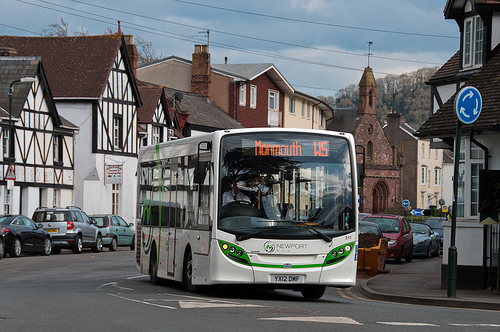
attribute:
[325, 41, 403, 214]
church — background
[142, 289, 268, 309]
markings — white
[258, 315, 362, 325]
markings — white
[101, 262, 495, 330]
markings — white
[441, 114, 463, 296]
pole — metal, green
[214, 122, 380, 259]
windscreen — large, glass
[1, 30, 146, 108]
roof — pitched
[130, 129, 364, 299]
bus — commuter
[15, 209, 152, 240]
cars — parked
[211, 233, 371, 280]
lines — green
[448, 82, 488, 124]
sign — blue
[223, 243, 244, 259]
bus headlights — pair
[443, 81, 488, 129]
sign — blue, white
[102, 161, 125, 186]
sign — elevated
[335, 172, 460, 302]
car — red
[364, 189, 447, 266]
cars — parked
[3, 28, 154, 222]
building — white, wood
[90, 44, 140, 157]
trim — dark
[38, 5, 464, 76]
sky — overcast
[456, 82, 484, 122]
sign — large, blue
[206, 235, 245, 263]
headlight — rear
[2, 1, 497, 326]
village —  quaint 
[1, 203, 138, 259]
cars — parked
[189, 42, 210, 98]
chimney — brown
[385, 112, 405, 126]
chimney — brown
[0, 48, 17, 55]
chimney — brown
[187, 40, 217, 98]
chimney — brick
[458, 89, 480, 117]
lines — circular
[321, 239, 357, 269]
panel — green, oval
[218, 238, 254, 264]
panel — green, oval